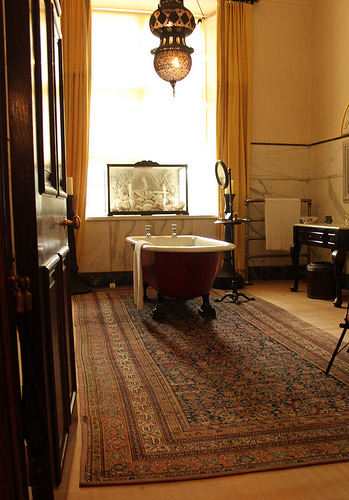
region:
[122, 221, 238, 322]
A red bathtub.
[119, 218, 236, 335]
The bathtub is in the middle of the floor.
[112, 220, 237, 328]
The bathtub is sitting on a rug.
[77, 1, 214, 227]
A large window is behind the tub.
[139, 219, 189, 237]
Two knobs are on the tub.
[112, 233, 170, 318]
A towel is hanging from the tub.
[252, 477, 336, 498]
The floor is wood.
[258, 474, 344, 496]
The floor is brown.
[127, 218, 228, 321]
The tub has feet.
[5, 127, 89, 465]
The door is open.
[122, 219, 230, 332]
a claw foot bathtub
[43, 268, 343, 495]
a large rug covering the floor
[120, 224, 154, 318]
a towel hanging over a bathtub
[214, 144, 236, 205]
a mirror on a stand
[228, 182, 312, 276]
a towel hanging on a towel rack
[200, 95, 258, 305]
a long yellow curtain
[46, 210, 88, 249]
a brass door knob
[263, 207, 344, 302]
a wooden table with a marble top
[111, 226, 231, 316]
a red and white bathtub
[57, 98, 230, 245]
a large window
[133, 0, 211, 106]
Chandelier hanging from the ceiling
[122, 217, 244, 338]
A bath tub with four legs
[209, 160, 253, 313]
Table with a mirror on top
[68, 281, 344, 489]
A brown rug with patters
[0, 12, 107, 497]
An open door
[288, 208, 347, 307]
Dark brown wooden table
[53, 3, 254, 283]
Window with light shining through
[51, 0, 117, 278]
Yellow curtains pulled aside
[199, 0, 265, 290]
Yellow curtains pulled aside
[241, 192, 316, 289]
Towel hanging on a towel warmer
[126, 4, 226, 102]
chandelear hanging from the ceiling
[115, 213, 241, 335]
free standing bath tub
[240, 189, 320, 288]
towel rack holding a towel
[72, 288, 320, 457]
rug under bath tub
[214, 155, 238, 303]
Mirror next to the bath tub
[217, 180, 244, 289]
Candle stick next to bath tub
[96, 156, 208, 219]
terrarium above bath tub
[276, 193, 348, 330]
dresser in the bathroom by the tub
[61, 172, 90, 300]
candle stand in the bathroom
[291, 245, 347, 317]
garbage can under dresser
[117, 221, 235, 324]
The bathtub is red and white.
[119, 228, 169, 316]
A towel is hanging on the tub.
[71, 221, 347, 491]
The tub is sitting on a rug.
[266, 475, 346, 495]
The wood is brown.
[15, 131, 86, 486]
The door is wood.